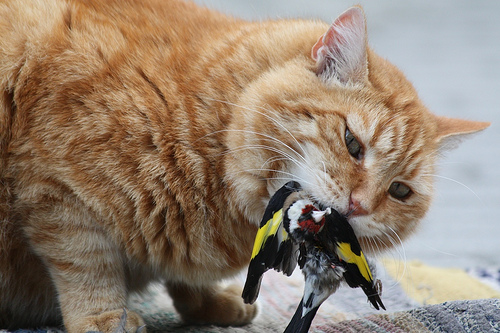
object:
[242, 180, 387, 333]
bird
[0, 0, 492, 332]
cat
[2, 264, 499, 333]
bench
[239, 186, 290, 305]
wing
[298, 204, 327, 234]
blood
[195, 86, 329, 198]
whiskers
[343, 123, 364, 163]
eye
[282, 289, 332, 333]
tail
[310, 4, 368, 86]
ear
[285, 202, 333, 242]
head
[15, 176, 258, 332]
legs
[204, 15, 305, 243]
neck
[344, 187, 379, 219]
nose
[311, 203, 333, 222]
beak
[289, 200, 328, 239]
face